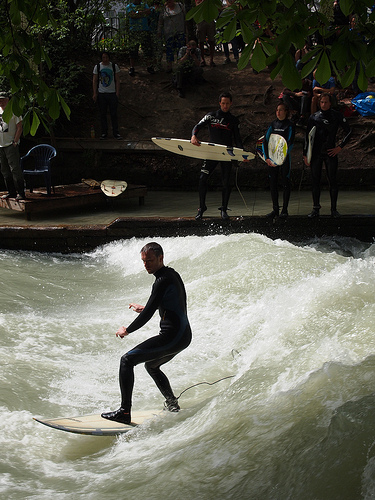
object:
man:
[92, 50, 123, 140]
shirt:
[93, 61, 121, 94]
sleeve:
[92, 64, 99, 75]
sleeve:
[114, 64, 121, 74]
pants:
[97, 93, 119, 134]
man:
[177, 40, 205, 98]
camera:
[188, 47, 199, 59]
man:
[191, 91, 250, 220]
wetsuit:
[191, 110, 250, 221]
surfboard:
[151, 137, 256, 162]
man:
[301, 92, 353, 219]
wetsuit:
[303, 107, 353, 218]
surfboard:
[306, 125, 316, 163]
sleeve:
[191, 110, 216, 136]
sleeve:
[337, 112, 353, 149]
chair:
[19, 144, 57, 195]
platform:
[0, 177, 149, 222]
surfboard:
[100, 179, 128, 197]